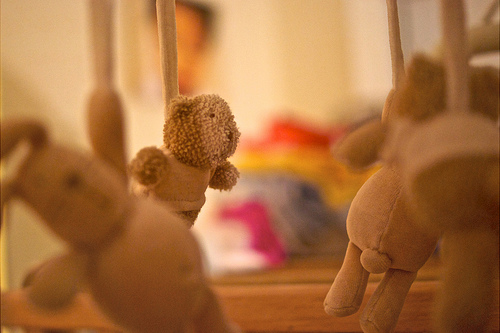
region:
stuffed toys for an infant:
[0, 51, 498, 331]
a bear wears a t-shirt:
[137, 93, 241, 223]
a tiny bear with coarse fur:
[131, 92, 246, 242]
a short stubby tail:
[362, 229, 396, 282]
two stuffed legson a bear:
[321, 234, 423, 331]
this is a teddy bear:
[126, 93, 267, 235]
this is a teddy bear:
[8, 120, 213, 320]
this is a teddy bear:
[322, 48, 497, 321]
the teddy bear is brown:
[126, 138, 201, 212]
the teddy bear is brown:
[70, 216, 153, 288]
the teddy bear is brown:
[140, 243, 207, 331]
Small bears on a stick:
[325, 38, 491, 297]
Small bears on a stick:
[111, 74, 267, 255]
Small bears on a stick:
[326, 55, 463, 299]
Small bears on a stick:
[13, 108, 222, 331]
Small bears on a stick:
[131, 65, 248, 238]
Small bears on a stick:
[348, 57, 494, 275]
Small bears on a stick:
[8, 9, 485, 294]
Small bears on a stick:
[11, 13, 494, 317]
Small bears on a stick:
[22, 46, 479, 331]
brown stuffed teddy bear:
[124, 85, 241, 235]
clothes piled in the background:
[190, 109, 364, 269]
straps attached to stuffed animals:
[83, 6, 482, 113]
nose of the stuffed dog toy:
[62, 169, 77, 184]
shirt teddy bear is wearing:
[145, 159, 207, 209]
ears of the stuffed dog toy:
[1, 116, 32, 198]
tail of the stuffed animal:
[353, 247, 387, 277]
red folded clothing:
[252, 112, 351, 149]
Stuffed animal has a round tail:
[310, 42, 455, 318]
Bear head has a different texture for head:
[164, 87, 252, 204]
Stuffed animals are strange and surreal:
[17, 7, 476, 332]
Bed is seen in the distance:
[194, 85, 394, 294]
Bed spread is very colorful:
[194, 111, 378, 280]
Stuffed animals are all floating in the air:
[20, 13, 491, 331]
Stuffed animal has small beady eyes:
[149, 85, 266, 190]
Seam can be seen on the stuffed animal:
[307, 84, 456, 314]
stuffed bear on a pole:
[124, 75, 277, 260]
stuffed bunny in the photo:
[2, 88, 212, 331]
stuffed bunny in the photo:
[301, 36, 496, 319]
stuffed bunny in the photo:
[333, 78, 498, 329]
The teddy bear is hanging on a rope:
[138, 5, 259, 245]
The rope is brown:
[151, 5, 207, 124]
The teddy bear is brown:
[127, 82, 279, 228]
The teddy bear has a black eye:
[147, 80, 263, 175]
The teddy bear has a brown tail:
[329, 168, 427, 288]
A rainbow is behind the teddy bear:
[130, 68, 417, 331]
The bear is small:
[111, 70, 263, 232]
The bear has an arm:
[140, 100, 287, 203]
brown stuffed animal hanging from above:
[133, 91, 237, 229]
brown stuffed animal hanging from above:
[320, 52, 449, 329]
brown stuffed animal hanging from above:
[395, 90, 497, 327]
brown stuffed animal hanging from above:
[132, 87, 242, 222]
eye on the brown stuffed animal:
[205, 108, 215, 120]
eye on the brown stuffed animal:
[35, 176, 50, 188]